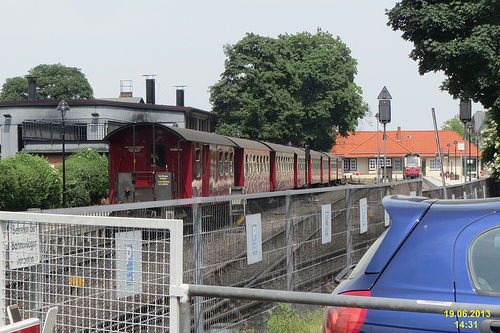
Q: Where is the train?
A: On the tracks.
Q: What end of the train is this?
A: Back.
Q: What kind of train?
A: Passenger train.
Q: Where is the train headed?
A: Train station.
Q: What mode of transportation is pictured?
A: Train.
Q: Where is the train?
A: On tracks.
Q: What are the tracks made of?
A: Metal.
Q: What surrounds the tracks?
A: Gravel.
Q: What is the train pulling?
A: Train cars.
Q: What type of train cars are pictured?
A: Passenger.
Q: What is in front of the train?
A: Fence.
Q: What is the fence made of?
A: Metal.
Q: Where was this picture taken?
A: Train yard.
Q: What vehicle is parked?
A: A car.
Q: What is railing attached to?
A: The fence.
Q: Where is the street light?
A: Next to train.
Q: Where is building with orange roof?
A: Between two trees.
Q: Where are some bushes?
A: Next to train.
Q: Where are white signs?
A: On the fence.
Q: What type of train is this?
A: Passenger train.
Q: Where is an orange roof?
A: On white building.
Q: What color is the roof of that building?
A: Orange.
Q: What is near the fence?
A: A patch of grass.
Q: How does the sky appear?
A: Clear.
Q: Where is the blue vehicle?
A: Near the fence.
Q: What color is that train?
A: Red.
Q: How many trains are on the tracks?
A: Two.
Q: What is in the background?
A: A building.